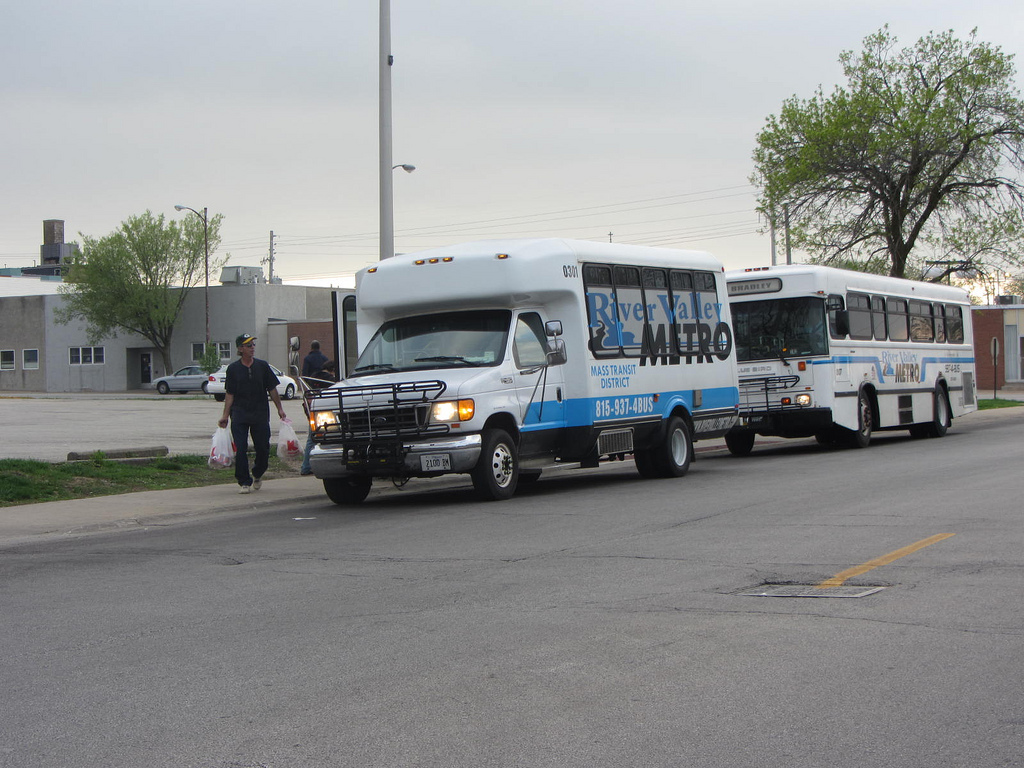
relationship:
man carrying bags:
[216, 332, 290, 494] [205, 419, 308, 476]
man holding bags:
[216, 332, 290, 494] [205, 419, 308, 476]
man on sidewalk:
[216, 332, 290, 494] [0, 406, 1023, 552]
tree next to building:
[51, 210, 232, 377] [0, 222, 357, 398]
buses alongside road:
[305, 238, 979, 509] [2, 417, 1022, 762]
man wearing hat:
[216, 332, 290, 494] [232, 331, 255, 353]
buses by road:
[305, 238, 979, 509] [2, 417, 1022, 762]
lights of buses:
[308, 402, 478, 437] [304, 237, 740, 508]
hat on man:
[232, 331, 255, 353] [216, 332, 290, 494]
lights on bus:
[779, 392, 811, 408] [724, 265, 978, 455]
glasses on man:
[240, 341, 257, 350] [216, 332, 290, 494]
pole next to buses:
[376, 0, 396, 263] [304, 237, 740, 508]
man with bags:
[216, 332, 290, 494] [205, 419, 308, 476]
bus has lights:
[724, 265, 978, 455] [779, 392, 811, 408]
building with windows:
[0, 222, 357, 398] [66, 345, 105, 367]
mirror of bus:
[836, 306, 849, 339] [724, 265, 978, 455]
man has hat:
[216, 332, 290, 494] [232, 331, 255, 353]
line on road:
[820, 529, 958, 591] [2, 417, 1022, 762]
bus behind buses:
[724, 265, 978, 455] [304, 237, 740, 508]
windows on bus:
[841, 289, 964, 346] [724, 265, 978, 455]